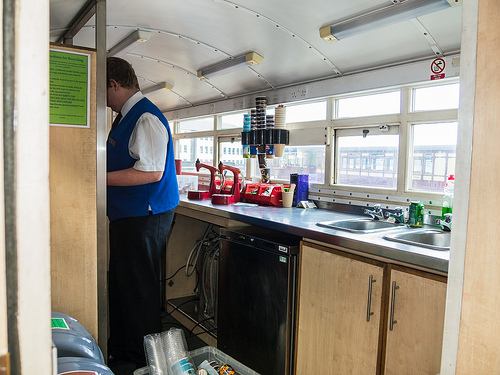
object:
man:
[104, 57, 180, 375]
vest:
[104, 95, 180, 222]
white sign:
[430, 57, 447, 75]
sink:
[383, 228, 449, 251]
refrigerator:
[217, 228, 295, 375]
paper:
[47, 49, 90, 128]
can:
[407, 201, 424, 227]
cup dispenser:
[241, 128, 290, 146]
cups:
[274, 144, 285, 157]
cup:
[281, 191, 293, 207]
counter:
[175, 191, 450, 274]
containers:
[242, 182, 291, 206]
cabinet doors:
[296, 239, 387, 375]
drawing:
[430, 58, 446, 74]